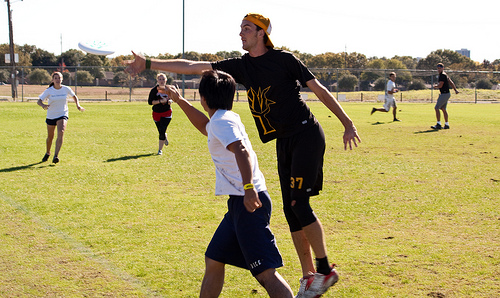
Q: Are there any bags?
A: No, there are no bags.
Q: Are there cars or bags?
A: No, there are no bags or cars.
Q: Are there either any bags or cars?
A: No, there are no bags or cars.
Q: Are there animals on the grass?
A: No, there is a person on the grass.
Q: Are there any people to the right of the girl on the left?
A: Yes, there is a person to the right of the girl.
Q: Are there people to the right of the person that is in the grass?
A: Yes, there is a person to the right of the girl.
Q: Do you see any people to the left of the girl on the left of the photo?
A: No, the person is to the right of the girl.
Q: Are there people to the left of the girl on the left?
A: No, the person is to the right of the girl.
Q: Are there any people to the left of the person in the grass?
A: No, the person is to the right of the girl.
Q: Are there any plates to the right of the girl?
A: No, there is a person to the right of the girl.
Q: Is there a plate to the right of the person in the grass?
A: No, there is a person to the right of the girl.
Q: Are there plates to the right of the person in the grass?
A: No, there is a person to the right of the girl.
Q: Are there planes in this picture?
A: No, there are no planes.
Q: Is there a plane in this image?
A: No, there are no airplanes.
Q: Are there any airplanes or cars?
A: No, there are no airplanes or cars.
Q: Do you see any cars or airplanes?
A: No, there are no airplanes or cars.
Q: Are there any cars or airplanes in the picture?
A: No, there are no airplanes or cars.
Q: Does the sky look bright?
A: Yes, the sky is bright.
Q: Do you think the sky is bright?
A: Yes, the sky is bright.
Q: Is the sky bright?
A: Yes, the sky is bright.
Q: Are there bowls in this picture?
A: No, there are no bowls.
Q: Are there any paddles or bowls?
A: No, there are no bowls or paddles.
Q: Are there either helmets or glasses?
A: No, there are no glasses or helmets.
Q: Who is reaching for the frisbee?
A: The man is reaching for the frisbee.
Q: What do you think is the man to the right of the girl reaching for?
A: The man is reaching for the frisbee.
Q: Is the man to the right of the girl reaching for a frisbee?
A: Yes, the man is reaching for a frisbee.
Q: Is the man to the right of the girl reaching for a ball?
A: No, the man is reaching for a frisbee.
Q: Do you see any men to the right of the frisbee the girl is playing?
A: Yes, there is a man to the right of the frisbee.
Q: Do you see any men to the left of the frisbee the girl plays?
A: No, the man is to the right of the frisbee.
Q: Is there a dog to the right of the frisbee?
A: No, there is a man to the right of the frisbee.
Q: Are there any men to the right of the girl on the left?
A: Yes, there is a man to the right of the girl.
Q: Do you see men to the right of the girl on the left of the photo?
A: Yes, there is a man to the right of the girl.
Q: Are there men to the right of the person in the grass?
A: Yes, there is a man to the right of the girl.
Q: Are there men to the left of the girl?
A: No, the man is to the right of the girl.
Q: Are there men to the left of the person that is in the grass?
A: No, the man is to the right of the girl.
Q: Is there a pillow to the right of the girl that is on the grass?
A: No, there is a man to the right of the girl.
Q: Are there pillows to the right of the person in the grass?
A: No, there is a man to the right of the girl.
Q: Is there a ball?
A: No, there are no balls.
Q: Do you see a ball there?
A: No, there are no balls.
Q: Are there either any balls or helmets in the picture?
A: No, there are no balls or helmets.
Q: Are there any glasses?
A: No, there are no glasses.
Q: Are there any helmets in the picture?
A: No, there are no helmets.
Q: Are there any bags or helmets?
A: No, there are no helmets or bags.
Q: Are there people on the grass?
A: Yes, there is a person on the grass.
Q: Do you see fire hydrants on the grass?
A: No, there is a person on the grass.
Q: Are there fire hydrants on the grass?
A: No, there is a person on the grass.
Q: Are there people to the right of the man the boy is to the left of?
A: Yes, there is a person to the right of the man.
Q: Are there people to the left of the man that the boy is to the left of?
A: No, the person is to the right of the man.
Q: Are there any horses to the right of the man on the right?
A: No, there is a person to the right of the man.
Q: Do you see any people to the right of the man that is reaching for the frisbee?
A: Yes, there is a person to the right of the man.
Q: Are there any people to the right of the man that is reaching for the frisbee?
A: Yes, there is a person to the right of the man.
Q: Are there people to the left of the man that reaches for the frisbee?
A: No, the person is to the right of the man.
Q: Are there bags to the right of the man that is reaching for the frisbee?
A: No, there is a person to the right of the man.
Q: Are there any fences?
A: Yes, there is a fence.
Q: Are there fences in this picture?
A: Yes, there is a fence.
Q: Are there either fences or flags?
A: Yes, there is a fence.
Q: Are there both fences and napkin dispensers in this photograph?
A: No, there is a fence but no napkin dispensers.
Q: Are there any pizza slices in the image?
A: No, there are no pizza slices.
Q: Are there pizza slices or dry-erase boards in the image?
A: No, there are no pizza slices or dry-erase boards.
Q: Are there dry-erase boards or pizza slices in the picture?
A: No, there are no pizza slices or dry-erase boards.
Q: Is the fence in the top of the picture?
A: Yes, the fence is in the top of the image.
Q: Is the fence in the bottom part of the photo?
A: No, the fence is in the top of the image.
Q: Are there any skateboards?
A: No, there are no skateboards.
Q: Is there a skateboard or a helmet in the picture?
A: No, there are no skateboards or helmets.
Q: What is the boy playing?
A: The boy is playing frisbee.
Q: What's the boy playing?
A: The boy is playing frisbee.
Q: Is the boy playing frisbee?
A: Yes, the boy is playing frisbee.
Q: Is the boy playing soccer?
A: No, the boy is playing frisbee.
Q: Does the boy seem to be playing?
A: Yes, the boy is playing.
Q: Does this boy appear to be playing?
A: Yes, the boy is playing.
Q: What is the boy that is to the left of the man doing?
A: The boy is playing.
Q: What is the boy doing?
A: The boy is playing.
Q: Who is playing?
A: The boy is playing.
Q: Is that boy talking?
A: No, the boy is playing.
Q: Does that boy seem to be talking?
A: No, the boy is playing.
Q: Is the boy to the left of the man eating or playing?
A: The boy is playing.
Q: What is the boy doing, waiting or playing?
A: The boy is playing.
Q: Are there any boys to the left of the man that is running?
A: Yes, there is a boy to the left of the man.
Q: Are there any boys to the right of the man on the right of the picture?
A: No, the boy is to the left of the man.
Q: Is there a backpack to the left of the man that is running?
A: No, there is a boy to the left of the man.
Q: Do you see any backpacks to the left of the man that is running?
A: No, there is a boy to the left of the man.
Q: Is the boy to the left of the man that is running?
A: Yes, the boy is to the left of the man.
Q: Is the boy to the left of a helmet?
A: No, the boy is to the left of the man.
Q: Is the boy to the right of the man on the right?
A: No, the boy is to the left of the man.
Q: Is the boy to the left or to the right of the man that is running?
A: The boy is to the left of the man.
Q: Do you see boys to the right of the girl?
A: Yes, there is a boy to the right of the girl.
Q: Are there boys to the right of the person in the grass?
A: Yes, there is a boy to the right of the girl.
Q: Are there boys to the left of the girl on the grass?
A: No, the boy is to the right of the girl.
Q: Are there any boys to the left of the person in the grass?
A: No, the boy is to the right of the girl.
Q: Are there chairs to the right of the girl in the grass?
A: No, there is a boy to the right of the girl.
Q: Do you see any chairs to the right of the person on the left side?
A: No, there is a boy to the right of the girl.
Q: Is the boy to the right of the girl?
A: Yes, the boy is to the right of the girl.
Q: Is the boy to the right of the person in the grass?
A: Yes, the boy is to the right of the girl.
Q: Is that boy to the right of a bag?
A: No, the boy is to the right of the girl.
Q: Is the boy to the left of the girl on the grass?
A: No, the boy is to the right of the girl.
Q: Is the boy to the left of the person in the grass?
A: No, the boy is to the right of the girl.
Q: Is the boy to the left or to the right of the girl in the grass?
A: The boy is to the right of the girl.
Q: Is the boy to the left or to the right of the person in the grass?
A: The boy is to the right of the girl.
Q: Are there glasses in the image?
A: No, there are no glasses.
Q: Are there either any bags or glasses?
A: No, there are no glasses or bags.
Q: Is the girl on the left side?
A: Yes, the girl is on the left of the image.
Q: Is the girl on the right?
A: No, the girl is on the left of the image.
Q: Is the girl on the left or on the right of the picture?
A: The girl is on the left of the image.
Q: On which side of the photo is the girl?
A: The girl is on the left of the image.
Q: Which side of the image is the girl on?
A: The girl is on the left of the image.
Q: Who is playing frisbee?
A: The girl is playing frisbee.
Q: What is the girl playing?
A: The girl is playing frisbee.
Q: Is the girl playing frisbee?
A: Yes, the girl is playing frisbee.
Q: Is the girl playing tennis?
A: No, the girl is playing frisbee.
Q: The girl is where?
A: The girl is on the grass.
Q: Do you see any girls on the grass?
A: Yes, there is a girl on the grass.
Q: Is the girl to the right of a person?
A: No, the girl is to the left of a person.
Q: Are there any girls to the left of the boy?
A: Yes, there is a girl to the left of the boy.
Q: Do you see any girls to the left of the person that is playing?
A: Yes, there is a girl to the left of the boy.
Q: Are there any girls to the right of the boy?
A: No, the girl is to the left of the boy.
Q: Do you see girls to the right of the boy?
A: No, the girl is to the left of the boy.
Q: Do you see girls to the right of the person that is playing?
A: No, the girl is to the left of the boy.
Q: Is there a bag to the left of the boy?
A: No, there is a girl to the left of the boy.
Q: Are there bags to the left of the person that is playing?
A: No, there is a girl to the left of the boy.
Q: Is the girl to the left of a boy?
A: Yes, the girl is to the left of a boy.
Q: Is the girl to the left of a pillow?
A: No, the girl is to the left of a boy.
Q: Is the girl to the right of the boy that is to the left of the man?
A: No, the girl is to the left of the boy.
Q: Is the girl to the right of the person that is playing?
A: No, the girl is to the left of the boy.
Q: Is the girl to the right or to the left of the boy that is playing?
A: The girl is to the left of the boy.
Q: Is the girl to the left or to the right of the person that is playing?
A: The girl is to the left of the boy.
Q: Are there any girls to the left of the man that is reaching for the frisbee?
A: Yes, there is a girl to the left of the man.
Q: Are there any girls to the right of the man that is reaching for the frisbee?
A: No, the girl is to the left of the man.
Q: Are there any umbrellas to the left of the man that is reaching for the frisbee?
A: No, there is a girl to the left of the man.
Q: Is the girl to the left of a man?
A: Yes, the girl is to the left of a man.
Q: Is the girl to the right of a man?
A: No, the girl is to the left of a man.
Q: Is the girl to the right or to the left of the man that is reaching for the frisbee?
A: The girl is to the left of the man.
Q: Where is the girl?
A: The girl is in the grass.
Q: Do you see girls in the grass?
A: Yes, there is a girl in the grass.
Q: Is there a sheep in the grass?
A: No, there is a girl in the grass.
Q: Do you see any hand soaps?
A: No, there are no hand soaps.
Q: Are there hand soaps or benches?
A: No, there are no hand soaps or benches.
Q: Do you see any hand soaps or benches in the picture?
A: No, there are no hand soaps or benches.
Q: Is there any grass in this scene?
A: Yes, there is grass.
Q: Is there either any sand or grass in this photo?
A: Yes, there is grass.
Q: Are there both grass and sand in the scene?
A: No, there is grass but no sand.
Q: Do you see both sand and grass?
A: No, there is grass but no sand.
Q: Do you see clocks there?
A: No, there are no clocks.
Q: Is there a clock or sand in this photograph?
A: No, there are no clocks or sand.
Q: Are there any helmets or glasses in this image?
A: No, there are no glasses or helmets.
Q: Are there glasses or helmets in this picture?
A: No, there are no glasses or helmets.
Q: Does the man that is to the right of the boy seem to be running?
A: Yes, the man is running.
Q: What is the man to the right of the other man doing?
A: The man is running.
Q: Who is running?
A: The man is running.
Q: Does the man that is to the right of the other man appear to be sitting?
A: No, the man is running.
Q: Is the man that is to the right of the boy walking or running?
A: The man is running.